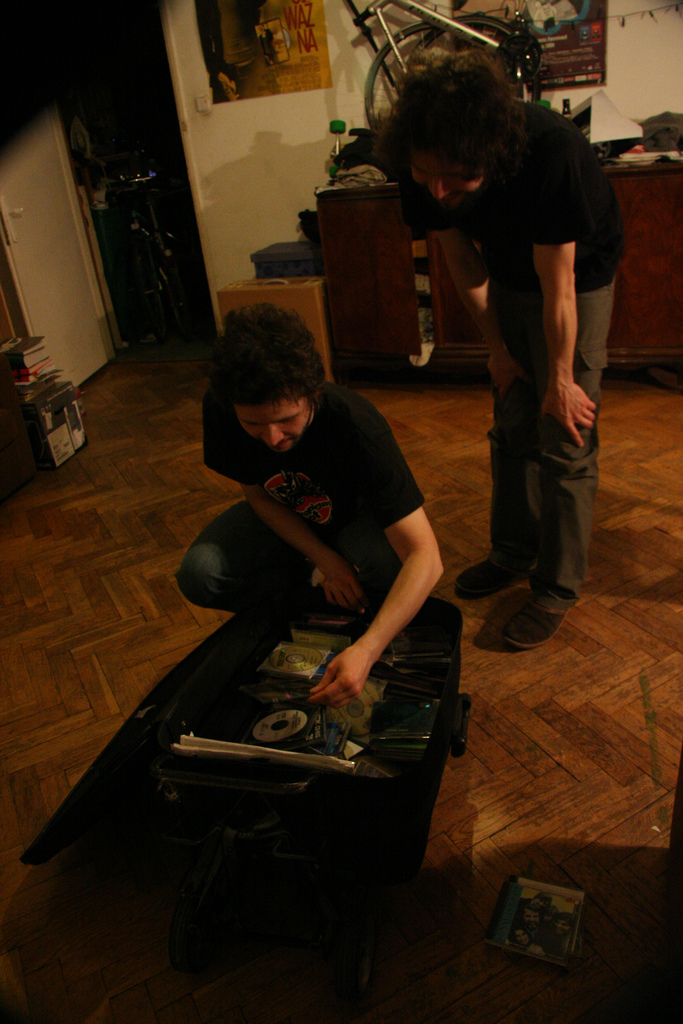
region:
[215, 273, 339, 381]
Light brown hard case with handle on top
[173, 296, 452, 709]
Man in black shirt squatting on floor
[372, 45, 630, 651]
Standing man bent over with hands on knees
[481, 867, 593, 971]
CD jewel cases laying on floor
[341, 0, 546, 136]
Bicycle hanging on wall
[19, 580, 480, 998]
Large black case with wheels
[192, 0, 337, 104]
Poster with writing on wall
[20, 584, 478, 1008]
Open black case containing compact discs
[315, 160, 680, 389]
Brown wooden cabinet with one door ajar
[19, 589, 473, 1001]
the suitcase is black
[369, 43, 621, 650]
the man is standing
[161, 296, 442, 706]
the man is squatting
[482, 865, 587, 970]
the cd's are on the floor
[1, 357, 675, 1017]
the floor is wooden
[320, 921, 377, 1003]
the wheel of the suitcase is black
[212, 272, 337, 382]
the box behind the squatting man is card board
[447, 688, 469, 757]
the handle of the suitcase is black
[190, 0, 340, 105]
the yellow and red poster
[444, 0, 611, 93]
the purple white and blue poster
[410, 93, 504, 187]
head of the man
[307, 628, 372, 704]
hand of the man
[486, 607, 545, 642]
shoe on the man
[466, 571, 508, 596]
shoe on the man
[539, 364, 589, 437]
hand of the man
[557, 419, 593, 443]
finger on the hand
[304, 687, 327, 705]
finger on the hand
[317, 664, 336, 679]
finger of the hand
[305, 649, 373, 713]
Hand of a man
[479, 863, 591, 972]
Music CD's are visible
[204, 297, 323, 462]
Head of a man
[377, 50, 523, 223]
Head of a man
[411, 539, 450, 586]
Elbow of a man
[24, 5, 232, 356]
Doorway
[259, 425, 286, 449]
Nose of a man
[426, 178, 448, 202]
Nose of a man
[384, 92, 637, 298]
Shirt on a man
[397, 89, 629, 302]
Black shirt on a man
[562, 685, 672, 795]
a tile in a floor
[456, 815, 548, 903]
a tile in a floor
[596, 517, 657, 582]
a tile in a floor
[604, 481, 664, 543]
a tile in a floor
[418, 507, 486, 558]
a tile in a floor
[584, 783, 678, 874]
a tile in a floor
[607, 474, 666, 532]
a tile in a floor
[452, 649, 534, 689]
a tile in a floor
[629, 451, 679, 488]
a tile in a floor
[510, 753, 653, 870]
old and dirty wooden parquet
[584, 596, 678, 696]
old and dirty wooden parquet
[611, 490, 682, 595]
old and dirty wooden parquet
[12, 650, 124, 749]
old and dirty wooden parquet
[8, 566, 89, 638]
old and dirty wooden parquet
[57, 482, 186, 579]
old and dirty wooden parquet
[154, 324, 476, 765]
a man looking for CDs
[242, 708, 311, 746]
A CD in some luggage.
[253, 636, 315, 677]
A CD in some luggage.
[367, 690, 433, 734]
A CD in some luggage.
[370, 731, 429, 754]
A CD in some luggage.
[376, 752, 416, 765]
A CD in some luggage.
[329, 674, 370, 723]
A CD in some luggage.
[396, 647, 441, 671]
A CD in some luggage.